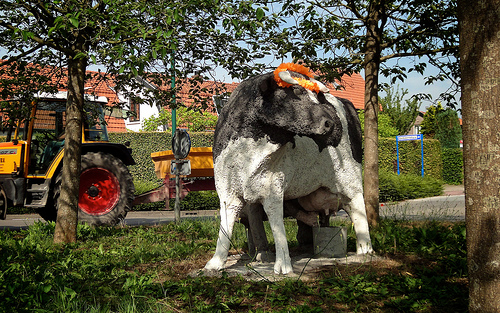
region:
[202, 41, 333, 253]
large cow statue in grass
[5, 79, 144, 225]
tracker in background behind tree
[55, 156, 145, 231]
black rubber tractor tire with red middle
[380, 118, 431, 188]
blue arch sign in background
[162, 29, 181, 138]
tall green metal pole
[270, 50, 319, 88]
orange lei on top of cow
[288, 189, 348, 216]
pink utters under cow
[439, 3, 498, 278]
large tree trunk on right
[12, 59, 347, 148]
houses in background with red roofs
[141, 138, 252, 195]
yellow trailer behind tractor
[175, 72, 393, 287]
A statue of a cow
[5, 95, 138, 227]
Large tractor in the background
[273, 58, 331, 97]
Cow wearing a lay on head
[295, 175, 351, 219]
Udders under the cow statue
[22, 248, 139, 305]
The ground is green and leafy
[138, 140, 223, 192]
Trailer pulled behind a tractor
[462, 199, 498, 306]
Shadow on the tree trunk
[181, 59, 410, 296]
The statue is white and black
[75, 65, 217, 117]
The roof of the building is clay colored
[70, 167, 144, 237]
The wheel is red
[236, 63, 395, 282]
Black and white cow.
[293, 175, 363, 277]
Cow udder with milk.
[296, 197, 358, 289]
Milking bucket under cow.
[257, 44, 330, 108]
Orange lei on cows head.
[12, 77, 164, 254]
Yellow tractor on road.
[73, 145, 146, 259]
Red wheel rim in tire.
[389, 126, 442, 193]
Blue posts in front of hedge.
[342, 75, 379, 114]
Red roof tiles on house.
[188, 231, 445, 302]
Cement slab under cow.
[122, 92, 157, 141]
Window in side of house.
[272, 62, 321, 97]
neon orange hawaiian lei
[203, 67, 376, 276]
realistic black and white cement cow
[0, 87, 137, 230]
yellow tractor with big wheels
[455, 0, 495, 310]
large trunk of a tree in the foreground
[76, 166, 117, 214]
big red tractor rim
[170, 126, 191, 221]
backward signs that can't be read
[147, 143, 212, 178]
yellowish gold box trailer for hauling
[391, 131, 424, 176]
narrow white rectangle sign with bright blue poles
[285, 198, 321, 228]
cement person milking the cement cow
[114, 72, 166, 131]
side of an off-white building with a window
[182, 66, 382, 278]
a cow standing under trees.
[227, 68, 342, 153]
a black cow head.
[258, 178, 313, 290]
a left front leg.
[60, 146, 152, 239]
a rear tractor tire.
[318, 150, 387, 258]
a left hind cow leg.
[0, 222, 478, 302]
a field of green grass.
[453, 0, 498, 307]
a tree in a park.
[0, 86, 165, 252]
a tractor near a cow.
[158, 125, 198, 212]
a road sign.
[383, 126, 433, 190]
a blue sign.